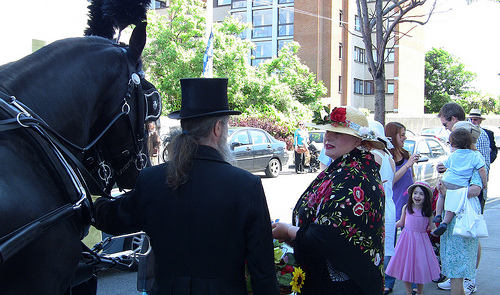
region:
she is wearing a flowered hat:
[301, 105, 377, 137]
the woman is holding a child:
[428, 117, 488, 294]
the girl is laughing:
[385, 179, 449, 291]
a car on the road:
[218, 113, 292, 182]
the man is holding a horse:
[0, 0, 178, 292]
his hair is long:
[156, 105, 241, 197]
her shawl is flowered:
[285, 146, 385, 284]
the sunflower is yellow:
[280, 264, 315, 294]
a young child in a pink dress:
[383, 172, 465, 292]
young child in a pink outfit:
[378, 180, 458, 292]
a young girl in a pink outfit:
[382, 179, 463, 294]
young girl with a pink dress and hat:
[379, 174, 459, 294]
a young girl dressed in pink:
[382, 169, 448, 293]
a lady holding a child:
[430, 113, 492, 293]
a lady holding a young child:
[430, 117, 491, 294]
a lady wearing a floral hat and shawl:
[271, 88, 405, 292]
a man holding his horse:
[2, 0, 287, 294]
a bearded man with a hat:
[86, 70, 288, 294]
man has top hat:
[174, 50, 234, 109]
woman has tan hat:
[294, 109, 392, 144]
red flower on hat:
[328, 88, 363, 126]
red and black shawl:
[309, 144, 381, 233]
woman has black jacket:
[287, 216, 362, 265]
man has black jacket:
[126, 138, 261, 292]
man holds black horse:
[20, 30, 270, 292]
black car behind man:
[210, 106, 294, 170]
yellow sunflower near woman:
[274, 259, 303, 285]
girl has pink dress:
[392, 202, 460, 292]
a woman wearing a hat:
[303, 101, 378, 162]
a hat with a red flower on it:
[310, 94, 374, 158]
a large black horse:
[0, 18, 164, 260]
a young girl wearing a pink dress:
[388, 173, 443, 291]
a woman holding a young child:
[430, 117, 483, 244]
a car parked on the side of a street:
[206, 118, 281, 185]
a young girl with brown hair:
[403, 174, 428, 223]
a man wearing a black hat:
[176, 58, 241, 150]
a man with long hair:
[141, 91, 226, 192]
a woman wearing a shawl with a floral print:
[292, 143, 381, 256]